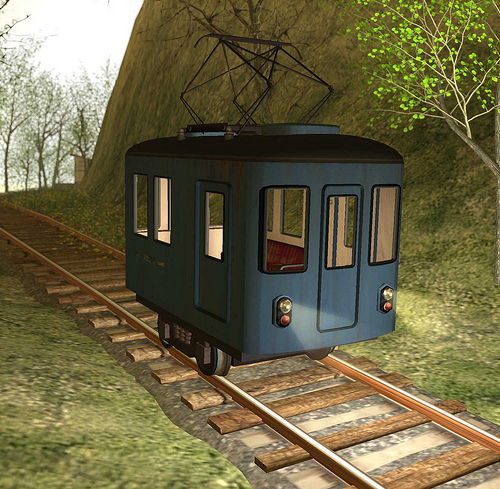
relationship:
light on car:
[278, 273, 342, 298] [123, 120, 405, 377]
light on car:
[281, 313, 293, 323] [123, 120, 405, 377]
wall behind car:
[82, 4, 454, 201] [123, 120, 405, 377]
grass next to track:
[6, 286, 226, 483] [3, 198, 498, 483]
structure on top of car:
[181, 32, 335, 124] [123, 120, 404, 375]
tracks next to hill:
[2, 195, 498, 487] [35, 3, 475, 287]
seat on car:
[265, 237, 304, 271] [123, 120, 405, 377]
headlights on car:
[264, 280, 398, 325] [100, 100, 422, 408]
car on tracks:
[123, 120, 405, 377] [2, 195, 498, 487]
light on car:
[282, 300, 393, 373] [123, 120, 405, 377]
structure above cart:
[173, 27, 336, 130] [119, 117, 407, 380]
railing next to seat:
[277, 255, 309, 274] [244, 231, 309, 279]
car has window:
[123, 120, 405, 377] [253, 174, 314, 277]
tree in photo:
[320, 0, 499, 187] [1, 6, 498, 488]